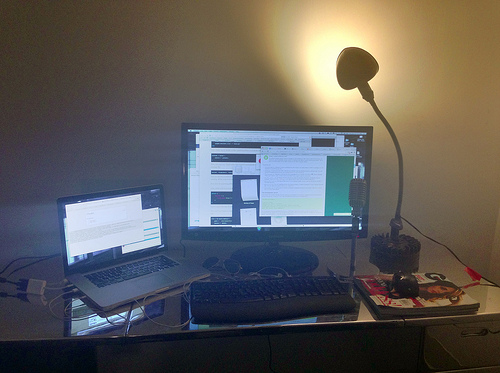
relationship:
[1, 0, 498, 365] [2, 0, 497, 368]
room has interior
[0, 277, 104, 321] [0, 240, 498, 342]
cords on desk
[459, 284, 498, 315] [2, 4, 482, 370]
desk pushed against wall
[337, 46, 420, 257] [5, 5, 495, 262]
lamp facing wall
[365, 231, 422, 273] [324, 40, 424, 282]
base of lamp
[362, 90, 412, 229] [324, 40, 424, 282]
arm of lamp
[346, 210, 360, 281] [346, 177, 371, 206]
stand of microphone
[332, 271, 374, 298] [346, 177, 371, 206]
base of microphone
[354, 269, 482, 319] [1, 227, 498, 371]
magazine on desk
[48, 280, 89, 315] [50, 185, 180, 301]
cords plugged in laptop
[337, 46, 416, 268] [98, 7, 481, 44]
lamp facing wall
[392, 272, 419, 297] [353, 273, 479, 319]
computer mouse on magazine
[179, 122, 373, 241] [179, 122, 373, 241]
computer monitor on computer monitor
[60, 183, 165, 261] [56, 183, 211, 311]
panel opened on computer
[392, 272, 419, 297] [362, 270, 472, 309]
computer mouse on magazines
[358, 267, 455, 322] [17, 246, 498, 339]
magazines on desk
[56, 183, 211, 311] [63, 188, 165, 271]
computer with panel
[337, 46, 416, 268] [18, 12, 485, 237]
lamp near wall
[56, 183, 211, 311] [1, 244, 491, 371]
computer on desk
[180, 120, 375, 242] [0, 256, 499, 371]
computer monitor on desk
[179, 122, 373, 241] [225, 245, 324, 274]
computer monitor has base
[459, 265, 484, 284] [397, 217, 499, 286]
red tag on black cord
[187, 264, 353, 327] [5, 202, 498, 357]
computer keyboard on desk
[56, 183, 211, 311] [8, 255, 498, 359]
computer on desk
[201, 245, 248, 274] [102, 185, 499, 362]
sunglasses on desk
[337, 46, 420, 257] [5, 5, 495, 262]
lamp on wall